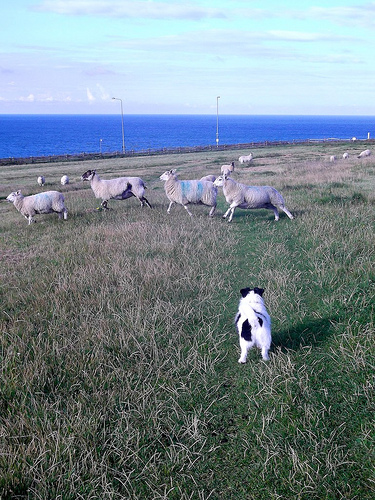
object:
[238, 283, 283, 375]
dog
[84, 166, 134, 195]
sheep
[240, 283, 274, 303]
ears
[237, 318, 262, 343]
spot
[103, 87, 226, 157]
streetlights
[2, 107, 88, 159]
water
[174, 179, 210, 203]
marks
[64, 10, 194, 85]
sky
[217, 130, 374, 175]
sheep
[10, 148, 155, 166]
fence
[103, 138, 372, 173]
distance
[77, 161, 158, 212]
sheep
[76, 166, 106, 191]
face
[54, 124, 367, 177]
background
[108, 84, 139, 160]
light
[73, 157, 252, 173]
field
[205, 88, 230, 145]
light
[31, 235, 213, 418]
grass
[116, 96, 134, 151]
post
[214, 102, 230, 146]
post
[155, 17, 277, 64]
clouds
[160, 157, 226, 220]
sheep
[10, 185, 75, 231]
sheep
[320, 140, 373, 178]
sheep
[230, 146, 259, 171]
sheep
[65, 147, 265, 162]
road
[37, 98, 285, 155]
ocean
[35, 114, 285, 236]
herd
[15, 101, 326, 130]
horizon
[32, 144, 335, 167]
coast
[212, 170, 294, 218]
sheep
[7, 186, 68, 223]
sheep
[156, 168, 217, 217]
sheep